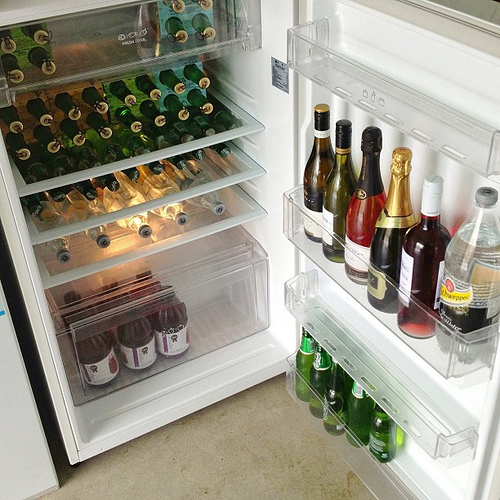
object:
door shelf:
[285, 17, 500, 179]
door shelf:
[282, 180, 499, 380]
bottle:
[302, 101, 336, 243]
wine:
[398, 218, 451, 340]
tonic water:
[436, 221, 499, 363]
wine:
[343, 188, 388, 279]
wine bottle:
[369, 147, 418, 315]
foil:
[384, 147, 415, 217]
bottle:
[345, 380, 372, 447]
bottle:
[308, 343, 333, 419]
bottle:
[397, 175, 451, 340]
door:
[282, 0, 499, 498]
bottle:
[343, 125, 389, 286]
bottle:
[433, 185, 499, 364]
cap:
[476, 186, 499, 204]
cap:
[421, 173, 446, 216]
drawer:
[42, 225, 274, 407]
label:
[438, 281, 474, 307]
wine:
[322, 162, 358, 262]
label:
[270, 55, 291, 95]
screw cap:
[334, 120, 352, 137]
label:
[396, 245, 415, 308]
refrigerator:
[0, 1, 499, 491]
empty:
[330, 24, 471, 100]